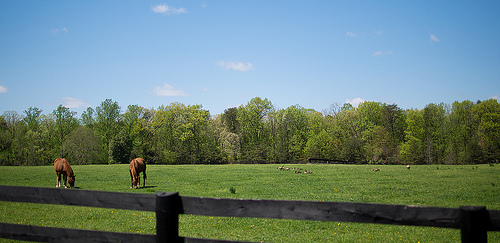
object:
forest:
[0, 95, 500, 166]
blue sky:
[0, 0, 498, 121]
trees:
[209, 114, 240, 163]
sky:
[3, 2, 498, 125]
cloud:
[369, 47, 399, 59]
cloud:
[142, 0, 197, 20]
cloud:
[148, 83, 190, 98]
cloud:
[426, 30, 444, 42]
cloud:
[0, 87, 18, 100]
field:
[0, 159, 500, 243]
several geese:
[276, 165, 413, 174]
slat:
[176, 235, 265, 243]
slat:
[0, 185, 158, 212]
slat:
[183, 195, 477, 230]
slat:
[0, 222, 157, 243]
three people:
[280, 15, 390, 58]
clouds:
[489, 95, 499, 100]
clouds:
[340, 22, 383, 35]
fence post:
[154, 191, 181, 242]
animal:
[129, 157, 147, 189]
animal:
[53, 157, 77, 189]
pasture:
[0, 162, 499, 241]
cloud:
[343, 96, 365, 111]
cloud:
[216, 57, 255, 73]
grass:
[126, 182, 145, 195]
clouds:
[148, 3, 186, 16]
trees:
[473, 98, 500, 162]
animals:
[276, 165, 313, 174]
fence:
[0, 184, 497, 243]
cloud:
[45, 25, 74, 38]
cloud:
[60, 94, 92, 108]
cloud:
[0, 82, 8, 94]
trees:
[398, 107, 427, 162]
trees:
[49, 104, 83, 158]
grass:
[309, 162, 497, 198]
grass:
[243, 221, 417, 241]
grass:
[347, 170, 408, 197]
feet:
[55, 186, 59, 188]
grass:
[150, 159, 257, 201]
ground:
[48, 167, 208, 195]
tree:
[182, 103, 207, 158]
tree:
[236, 97, 274, 158]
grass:
[134, 177, 175, 201]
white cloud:
[159, 84, 188, 97]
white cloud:
[213, 54, 243, 74]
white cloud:
[145, 2, 172, 12]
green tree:
[299, 121, 349, 165]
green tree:
[45, 103, 79, 156]